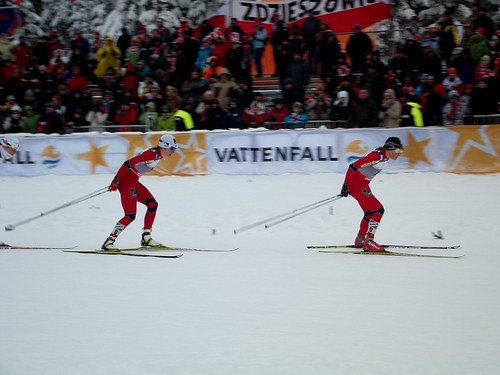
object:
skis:
[316, 248, 469, 259]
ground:
[0, 169, 499, 374]